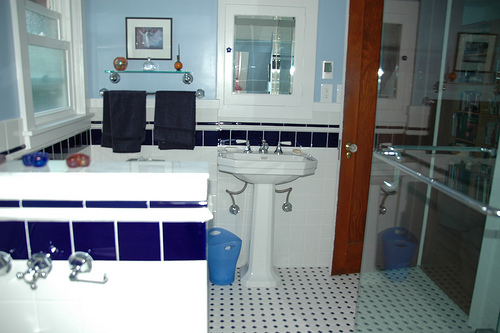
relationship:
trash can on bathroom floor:
[204, 224, 242, 286] [211, 262, 478, 330]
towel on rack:
[100, 91, 146, 155] [101, 90, 202, 99]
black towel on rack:
[154, 90, 196, 150] [101, 90, 202, 99]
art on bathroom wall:
[126, 17, 173, 61] [80, 0, 347, 268]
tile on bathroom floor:
[207, 264, 462, 329] [211, 262, 478, 330]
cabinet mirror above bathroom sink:
[232, 10, 297, 95] [216, 146, 317, 288]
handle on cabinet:
[226, 47, 233, 53] [218, 5, 316, 120]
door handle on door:
[343, 140, 362, 159] [330, 0, 385, 276]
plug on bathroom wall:
[320, 84, 332, 103] [316, 3, 344, 105]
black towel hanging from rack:
[154, 90, 196, 150] [101, 90, 202, 99]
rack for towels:
[99, 94, 203, 149] [99, 93, 202, 153]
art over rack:
[126, 17, 173, 61] [99, 94, 203, 149]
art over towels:
[126, 17, 173, 61] [99, 93, 202, 153]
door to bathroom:
[332, 3, 384, 276] [5, 5, 485, 330]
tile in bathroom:
[5, 198, 204, 261] [5, 5, 485, 330]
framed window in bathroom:
[25, 8, 71, 114] [5, 5, 485, 330]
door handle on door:
[344, 141, 358, 158] [332, 3, 384, 276]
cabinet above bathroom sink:
[215, 5, 316, 125] [215, 152, 319, 289]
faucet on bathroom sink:
[235, 135, 295, 154] [215, 152, 319, 289]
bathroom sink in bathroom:
[215, 152, 319, 289] [5, 5, 485, 330]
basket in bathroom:
[209, 225, 241, 284] [5, 5, 485, 330]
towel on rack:
[106, 92, 146, 149] [98, 85, 203, 105]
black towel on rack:
[154, 90, 196, 150] [96, 88, 209, 98]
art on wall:
[126, 17, 173, 61] [90, 5, 380, 266]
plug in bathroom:
[316, 84, 336, 103] [5, 5, 485, 330]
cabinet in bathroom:
[215, 5, 316, 125] [5, 5, 485, 330]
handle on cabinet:
[223, 44, 233, 52] [215, 5, 316, 125]